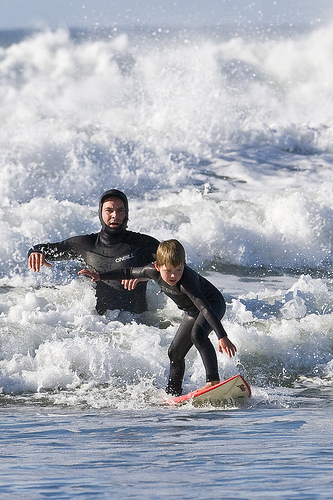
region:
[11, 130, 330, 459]
a man standing in the water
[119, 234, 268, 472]
a boy on a surfboard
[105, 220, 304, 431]
a young boy on a surfboard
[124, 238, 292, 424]
a child on a surfboard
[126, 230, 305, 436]
a boy riding a surfboard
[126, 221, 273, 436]
a child riding a surfboard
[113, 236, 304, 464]
a boy wearing a wetsuit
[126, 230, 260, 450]
a young boy wearing a wetsuit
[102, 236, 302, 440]
a child wearing a wetsuit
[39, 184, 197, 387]
a man wearing a wetsuit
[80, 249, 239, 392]
little boy on surfboard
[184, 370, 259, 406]
white surdboard with red edge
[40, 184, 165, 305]
man wearing black wetsuit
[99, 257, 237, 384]
black wetsuit of child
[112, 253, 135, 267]
white lettering on black wetsuit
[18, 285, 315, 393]
wave child is surfing on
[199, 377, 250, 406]
white bottom of surfboard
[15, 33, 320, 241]
waves crashing behind man wearing wetsuit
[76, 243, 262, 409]
little boy surfing a wave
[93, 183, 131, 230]
hood of black wetsuit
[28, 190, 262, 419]
two people in the ocean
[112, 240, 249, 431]
small kid on board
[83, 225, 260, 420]
small kid surfing in ocean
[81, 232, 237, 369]
small kid wearing wet suit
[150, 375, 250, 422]
red and white short board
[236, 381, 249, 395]
logo beneath surf board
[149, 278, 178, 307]
zipper on front of wet suit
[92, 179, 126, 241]
hoodie on man's head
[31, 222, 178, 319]
black wet suit on man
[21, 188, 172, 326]
man standing in white water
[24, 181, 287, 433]
man showing boy how to surf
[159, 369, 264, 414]
surfboard in the ocean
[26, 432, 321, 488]
blue waters of the ocean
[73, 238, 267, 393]
boy surfing in the water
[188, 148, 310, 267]
waves crashing in the ocean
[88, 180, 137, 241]
head of a male surfer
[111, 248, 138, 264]
Oakley name on wetsuit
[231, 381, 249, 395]
design on back of surfboard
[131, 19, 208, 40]
water splashing from the waves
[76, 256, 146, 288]
right arm of surfer boy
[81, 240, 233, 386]
child trying to stand on surfboard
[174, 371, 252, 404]
red edge of surfboard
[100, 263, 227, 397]
full body black wetsuit of child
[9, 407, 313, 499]
calm waters in front of surfer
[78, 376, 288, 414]
white spray kicked up by surfboard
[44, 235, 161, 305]
black wetsuit man is wearing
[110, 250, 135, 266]
white logo on black wetsuit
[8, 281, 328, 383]
white foam of wave child is riding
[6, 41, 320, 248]
waves behind man standing in ocean